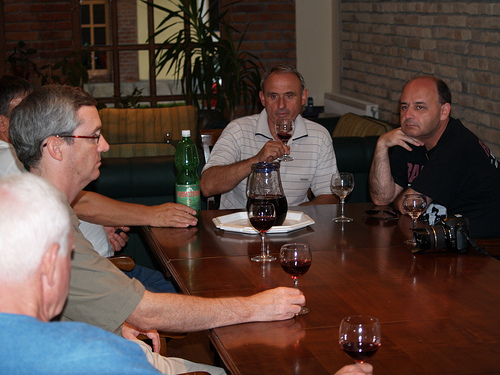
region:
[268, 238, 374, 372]
multiple glasses of full wine bottles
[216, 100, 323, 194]
white and black striped shirt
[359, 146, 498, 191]
black t shirt on man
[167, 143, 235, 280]
green plastic bottle on table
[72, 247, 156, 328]
tan colored shirt on man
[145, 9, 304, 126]
green plant in back of resturant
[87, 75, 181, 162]
green and yellow striped couch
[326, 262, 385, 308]
dark brown colored table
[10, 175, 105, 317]
white hair on older man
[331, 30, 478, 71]
tan colored brick on wall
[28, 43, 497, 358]
men sitting at a table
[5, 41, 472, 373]
men sitting at a brown table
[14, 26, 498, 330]
group of men sitting at a table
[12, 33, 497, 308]
men drinking wine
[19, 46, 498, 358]
men at a table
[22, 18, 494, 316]
men drinking at a table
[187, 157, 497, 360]
wine glasses on a tabe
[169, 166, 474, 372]
wine glasses on a brown table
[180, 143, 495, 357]
a table with wine glasses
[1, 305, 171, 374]
Man is wearing a shirt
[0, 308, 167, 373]
Man is wearing a blue shirt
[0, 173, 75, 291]
Man is has gray hair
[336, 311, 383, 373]
Man is holding a glass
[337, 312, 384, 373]
Man is holding a glass of wine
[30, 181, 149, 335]
Man is wearing a gray shirt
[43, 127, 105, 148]
Man is wearing glasses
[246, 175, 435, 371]
Glasses of wine on the table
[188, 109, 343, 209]
Man is wearing a striped shirt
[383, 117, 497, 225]
Man is wearing a black shirt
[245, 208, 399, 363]
the glasses are three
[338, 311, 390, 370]
wine is on the glass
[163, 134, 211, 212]
the bottle is green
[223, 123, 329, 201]
the shirt is white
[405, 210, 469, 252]
camera is on the table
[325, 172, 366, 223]
white wine is in glass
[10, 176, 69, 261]
hair is white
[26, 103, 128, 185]
man has glasses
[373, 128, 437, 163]
hand on chin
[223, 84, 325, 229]
person drinking wine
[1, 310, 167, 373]
The shirt is light blue.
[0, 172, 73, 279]
The man's hair is white.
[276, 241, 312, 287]
The glass is filled with wine.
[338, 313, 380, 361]
The glass is filled with wine.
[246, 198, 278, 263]
The glass is filled with wine.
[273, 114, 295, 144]
The glass is filled with wine.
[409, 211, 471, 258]
A camera sits on the table.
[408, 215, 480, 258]
The camera is black.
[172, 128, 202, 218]
The bottle is green.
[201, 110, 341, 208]
The shirt is white with stripes.